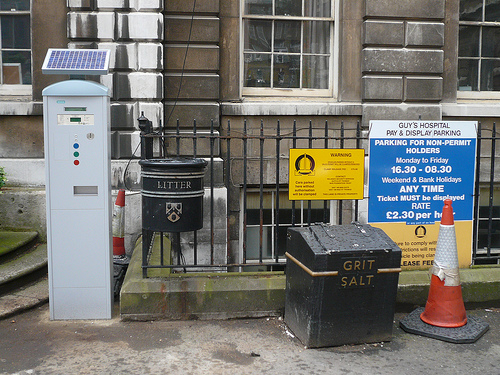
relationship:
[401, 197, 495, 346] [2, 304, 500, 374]
safety cone on sidewalk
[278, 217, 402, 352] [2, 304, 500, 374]
salt box on sidewalk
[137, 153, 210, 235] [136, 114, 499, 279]
litter bin on fence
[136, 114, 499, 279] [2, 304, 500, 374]
fence by sidewalk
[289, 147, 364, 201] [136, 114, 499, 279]
sign on fence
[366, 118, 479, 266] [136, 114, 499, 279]
sign on fence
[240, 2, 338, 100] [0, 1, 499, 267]
window on building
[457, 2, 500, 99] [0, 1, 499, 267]
window on building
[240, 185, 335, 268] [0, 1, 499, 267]
window on building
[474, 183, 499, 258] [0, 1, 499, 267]
window on building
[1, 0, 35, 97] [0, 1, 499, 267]
window on building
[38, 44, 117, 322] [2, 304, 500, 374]
ticket meter on sidewalk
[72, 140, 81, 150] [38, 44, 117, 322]
button on ticket meter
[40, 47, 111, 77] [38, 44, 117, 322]
solar power panel on ticket meter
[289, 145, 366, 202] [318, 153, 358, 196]
sign has black lettering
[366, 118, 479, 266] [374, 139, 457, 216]
sign has white lettering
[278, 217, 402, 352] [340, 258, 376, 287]
salt box has gold lettering